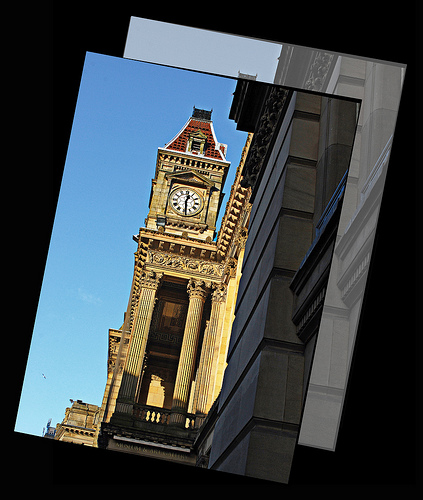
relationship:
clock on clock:
[170, 186, 205, 217] [169, 187, 204, 216]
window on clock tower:
[182, 131, 221, 160] [89, 104, 233, 468]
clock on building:
[166, 178, 208, 218] [54, 99, 253, 465]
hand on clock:
[185, 193, 191, 213] [168, 183, 205, 219]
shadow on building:
[104, 365, 207, 453] [41, 106, 262, 455]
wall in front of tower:
[229, 248, 269, 442] [101, 94, 230, 438]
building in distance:
[131, 116, 218, 383] [23, 360, 101, 456]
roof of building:
[163, 120, 222, 165] [88, 98, 241, 457]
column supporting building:
[109, 267, 164, 430] [53, 76, 361, 481]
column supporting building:
[160, 274, 211, 433] [78, 103, 248, 468]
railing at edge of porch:
[115, 395, 213, 445] [105, 404, 196, 447]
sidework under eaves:
[133, 244, 219, 281] [235, 99, 278, 128]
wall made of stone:
[229, 248, 269, 442] [216, 97, 333, 449]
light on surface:
[198, 288, 238, 412] [192, 274, 234, 414]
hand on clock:
[185, 194, 191, 214] [168, 184, 207, 217]